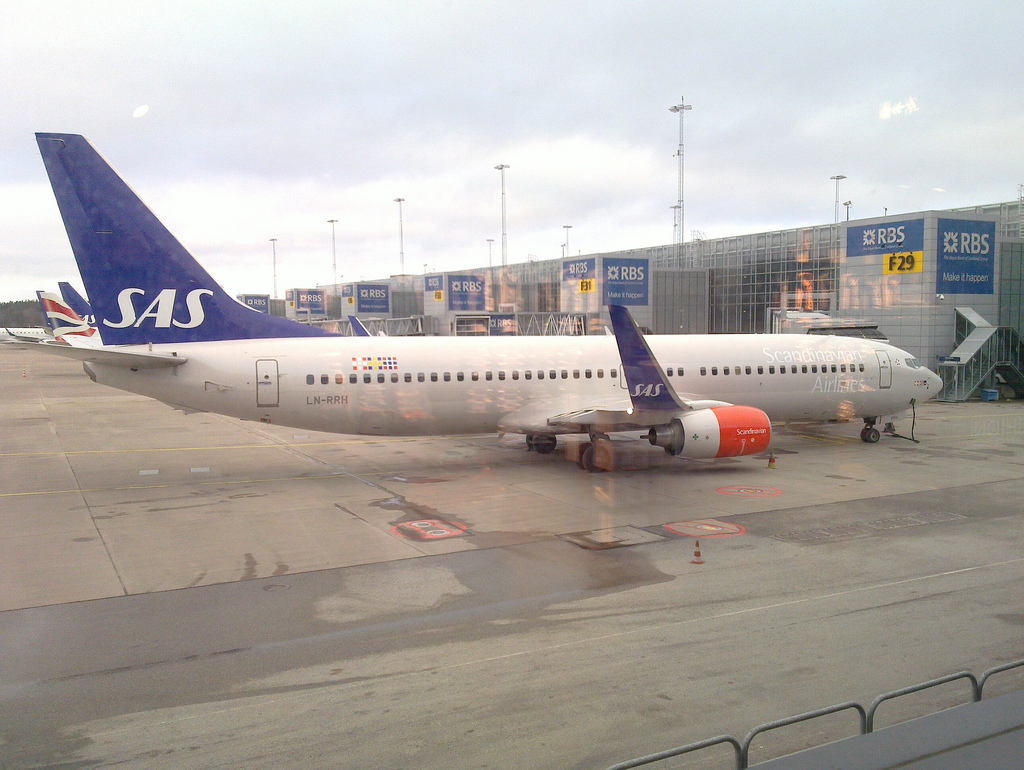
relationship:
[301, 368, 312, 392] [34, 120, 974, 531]
window on plane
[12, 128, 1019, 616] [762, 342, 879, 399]
plane has window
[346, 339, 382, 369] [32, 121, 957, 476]
window on plane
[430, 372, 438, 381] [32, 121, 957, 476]
window on plane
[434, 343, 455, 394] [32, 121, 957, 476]
window on plane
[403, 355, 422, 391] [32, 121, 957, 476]
window on plane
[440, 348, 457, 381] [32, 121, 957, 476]
window on plane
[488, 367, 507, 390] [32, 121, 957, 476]
window on plane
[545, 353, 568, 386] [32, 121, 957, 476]
window on plane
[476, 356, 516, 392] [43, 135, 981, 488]
window on plane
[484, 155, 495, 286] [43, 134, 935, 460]
poles behind plane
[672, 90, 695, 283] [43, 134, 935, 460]
poles behind plane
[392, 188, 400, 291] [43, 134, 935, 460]
poles behind plane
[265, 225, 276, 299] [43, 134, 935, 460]
poles behind plane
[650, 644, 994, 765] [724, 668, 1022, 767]
rail on walkway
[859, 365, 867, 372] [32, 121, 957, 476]
window on plane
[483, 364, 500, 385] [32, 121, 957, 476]
window on plane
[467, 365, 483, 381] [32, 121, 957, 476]
window on plane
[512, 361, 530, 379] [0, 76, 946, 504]
window on plane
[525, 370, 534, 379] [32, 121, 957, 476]
window on plane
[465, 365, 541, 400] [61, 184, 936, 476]
window on plane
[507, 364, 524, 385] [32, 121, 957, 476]
window on plane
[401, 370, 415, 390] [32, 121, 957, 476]
window on plane